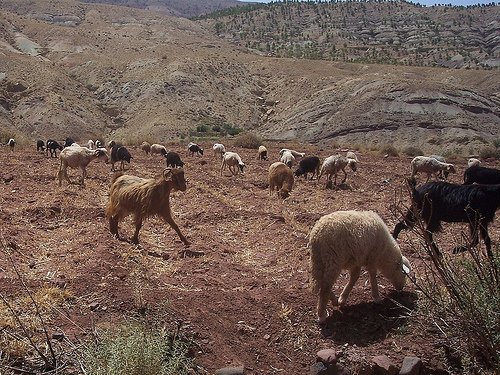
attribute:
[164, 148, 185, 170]
goat — black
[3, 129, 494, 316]
sheep — unshave, white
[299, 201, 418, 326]
sheep — domesticated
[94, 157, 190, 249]
goat — domesticated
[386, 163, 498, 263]
goat — black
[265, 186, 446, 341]
sheep — white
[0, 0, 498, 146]
hills — in background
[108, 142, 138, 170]
goat — black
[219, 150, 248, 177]
sheep — white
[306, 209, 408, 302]
goat — white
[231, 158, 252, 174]
head — black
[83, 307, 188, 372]
shrub — small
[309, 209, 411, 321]
sheep — white, female, domesticated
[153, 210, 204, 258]
foot — goat's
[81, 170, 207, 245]
goat — domesticated, male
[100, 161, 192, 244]
goat — brown